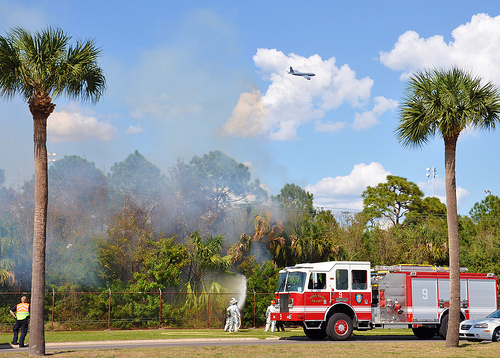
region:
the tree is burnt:
[239, 227, 291, 269]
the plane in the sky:
[275, 58, 336, 98]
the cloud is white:
[315, 62, 359, 95]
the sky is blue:
[300, 22, 332, 40]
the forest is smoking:
[42, 140, 302, 341]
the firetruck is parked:
[248, 211, 496, 334]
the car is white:
[457, 302, 497, 345]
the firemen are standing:
[215, 295, 252, 336]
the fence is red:
[95, 288, 122, 330]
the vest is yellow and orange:
[7, 297, 33, 322]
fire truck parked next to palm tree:
[269, 247, 490, 322]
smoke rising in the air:
[6, 10, 274, 256]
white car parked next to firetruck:
[444, 282, 496, 353]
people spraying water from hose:
[188, 257, 260, 339]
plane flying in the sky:
[258, 43, 335, 117]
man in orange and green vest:
[6, 286, 48, 353]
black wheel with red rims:
[325, 311, 359, 343]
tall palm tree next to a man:
[4, 22, 88, 357]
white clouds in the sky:
[217, 5, 498, 149]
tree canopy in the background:
[9, 142, 273, 203]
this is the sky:
[108, 0, 193, 54]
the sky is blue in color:
[117, 27, 197, 47]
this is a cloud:
[265, 82, 321, 128]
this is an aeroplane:
[283, 61, 317, 80]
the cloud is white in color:
[276, 88, 296, 105]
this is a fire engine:
[276, 260, 436, 334]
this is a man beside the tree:
[6, 294, 28, 346]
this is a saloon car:
[461, 313, 498, 339]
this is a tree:
[446, 72, 470, 343]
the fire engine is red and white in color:
[290, 265, 372, 308]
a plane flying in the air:
[286, 64, 316, 81]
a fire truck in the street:
[271, 265, 496, 341]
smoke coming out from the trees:
[26, 167, 297, 282]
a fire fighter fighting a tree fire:
[208, 277, 252, 334]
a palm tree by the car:
[398, 74, 490, 356]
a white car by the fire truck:
[457, 300, 499, 342]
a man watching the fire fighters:
[6, 292, 32, 349]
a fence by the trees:
[48, 292, 298, 337]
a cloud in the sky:
[224, 55, 371, 120]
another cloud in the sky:
[311, 158, 416, 218]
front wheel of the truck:
[331, 318, 346, 338]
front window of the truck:
[284, 275, 302, 292]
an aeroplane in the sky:
[290, 61, 316, 87]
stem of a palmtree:
[21, 258, 48, 350]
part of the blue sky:
[135, 1, 195, 122]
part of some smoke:
[148, 152, 253, 230]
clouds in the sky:
[448, 12, 498, 63]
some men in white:
[222, 297, 248, 332]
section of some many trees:
[65, 150, 190, 293]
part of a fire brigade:
[256, 227, 396, 331]